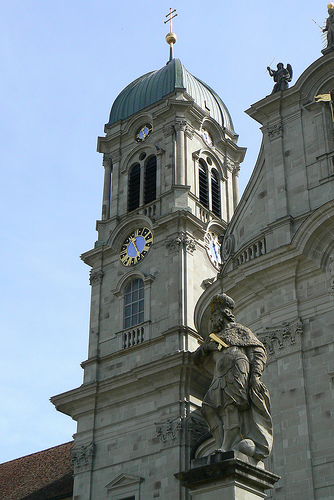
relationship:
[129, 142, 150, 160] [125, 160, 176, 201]
triangle above window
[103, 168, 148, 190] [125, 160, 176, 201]
shutters on window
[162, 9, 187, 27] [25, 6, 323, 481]
vane on building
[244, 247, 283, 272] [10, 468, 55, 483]
carvings on wall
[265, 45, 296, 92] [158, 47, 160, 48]
statue on pole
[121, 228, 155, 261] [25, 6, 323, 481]
clock on building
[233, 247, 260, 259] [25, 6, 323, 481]
cross on building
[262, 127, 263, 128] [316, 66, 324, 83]
bells in tower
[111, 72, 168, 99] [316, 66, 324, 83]
roof of tower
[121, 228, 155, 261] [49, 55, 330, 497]
clock on building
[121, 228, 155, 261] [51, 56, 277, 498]
clock on building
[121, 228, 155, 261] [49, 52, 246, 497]
clock on building